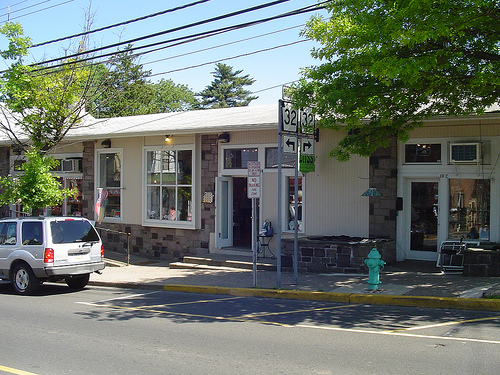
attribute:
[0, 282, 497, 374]
road — asphalt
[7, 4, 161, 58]
blue sky — bright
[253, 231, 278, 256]
table — small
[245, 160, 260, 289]
sign — no parking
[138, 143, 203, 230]
window — white, paned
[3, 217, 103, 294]
car — parked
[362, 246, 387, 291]
fire hydrant — green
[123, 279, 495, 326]
lines — yellow, parking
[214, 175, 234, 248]
door — white, open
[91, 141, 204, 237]
windows — white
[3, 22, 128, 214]
tree — green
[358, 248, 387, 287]
fire hydrant — green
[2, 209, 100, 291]
car — gray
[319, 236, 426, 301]
hydrant — green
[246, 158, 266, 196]
sign — white, red, street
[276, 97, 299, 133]
sign — black and white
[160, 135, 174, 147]
light bulb — Bare 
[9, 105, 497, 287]
building — one story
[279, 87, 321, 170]
signs — traffic, directional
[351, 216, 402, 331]
hydrant — green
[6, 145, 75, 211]
leaves — green, bright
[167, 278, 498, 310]
sidewalk edge — yellow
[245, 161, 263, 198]
sign — street sign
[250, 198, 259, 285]
pole — metal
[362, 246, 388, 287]
fire hydrant — turquoise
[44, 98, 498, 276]
building — one story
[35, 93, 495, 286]
building — one story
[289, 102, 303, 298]
pole — metal